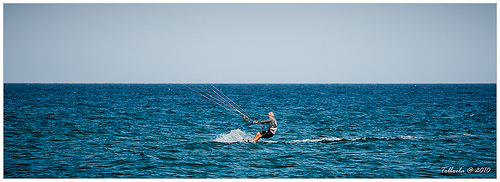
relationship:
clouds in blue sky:
[347, 18, 407, 40] [4, 3, 499, 82]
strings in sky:
[87, 16, 248, 122] [81, 19, 494, 74]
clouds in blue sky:
[4, 4, 499, 84] [4, 3, 499, 82]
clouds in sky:
[4, 4, 499, 84] [290, 18, 446, 98]